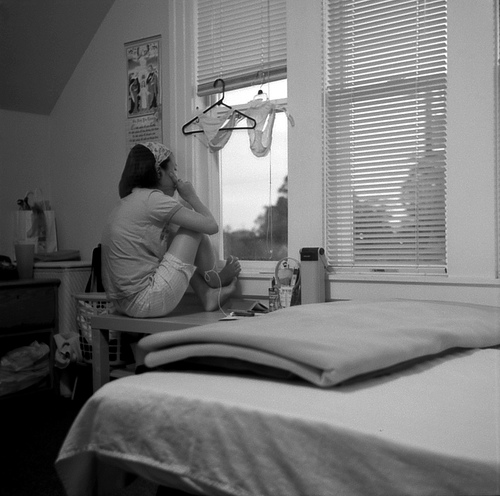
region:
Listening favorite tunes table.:
[102, 131, 240, 308]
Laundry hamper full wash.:
[68, 285, 131, 368]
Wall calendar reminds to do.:
[115, 32, 175, 142]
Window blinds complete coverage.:
[316, 3, 452, 276]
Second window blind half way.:
[174, 2, 318, 96]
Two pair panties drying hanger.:
[177, 80, 292, 160]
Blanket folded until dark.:
[135, 286, 499, 363]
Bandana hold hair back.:
[105, 134, 197, 198]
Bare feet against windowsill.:
[200, 245, 245, 311]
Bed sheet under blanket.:
[49, 373, 496, 495]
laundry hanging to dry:
[180, 86, 279, 156]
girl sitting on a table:
[102, 144, 239, 314]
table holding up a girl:
[82, 300, 251, 390]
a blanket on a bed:
[140, 290, 498, 388]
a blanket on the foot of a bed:
[140, 297, 498, 388]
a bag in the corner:
[10, 197, 60, 267]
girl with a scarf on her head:
[117, 136, 180, 202]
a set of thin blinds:
[320, 0, 447, 271]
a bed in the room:
[50, 299, 499, 491]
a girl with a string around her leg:
[192, 252, 243, 296]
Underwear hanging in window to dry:
[178, 66, 301, 158]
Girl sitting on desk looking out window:
[93, 137, 248, 321]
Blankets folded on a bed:
[129, 272, 499, 392]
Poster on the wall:
[110, 31, 175, 148]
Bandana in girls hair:
[97, 126, 193, 201]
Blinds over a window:
[322, 2, 458, 272]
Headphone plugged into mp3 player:
[184, 231, 251, 325]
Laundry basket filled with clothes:
[71, 284, 125, 363]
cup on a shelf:
[6, 237, 58, 291]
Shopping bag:
[16, 182, 67, 263]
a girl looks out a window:
[92, 114, 287, 348]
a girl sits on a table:
[84, 113, 289, 328]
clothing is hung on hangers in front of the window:
[172, 79, 309, 175]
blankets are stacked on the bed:
[158, 277, 483, 441]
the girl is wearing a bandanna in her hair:
[75, 128, 328, 324]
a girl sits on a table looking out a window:
[96, 82, 429, 354]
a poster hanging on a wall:
[99, 22, 193, 197]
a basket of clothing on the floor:
[63, 274, 163, 391]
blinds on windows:
[170, 13, 470, 309]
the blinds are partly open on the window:
[169, 13, 366, 297]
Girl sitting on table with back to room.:
[101, 130, 254, 324]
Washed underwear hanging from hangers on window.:
[182, 72, 297, 164]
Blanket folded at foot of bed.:
[137, 292, 498, 385]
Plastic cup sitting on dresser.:
[10, 235, 47, 285]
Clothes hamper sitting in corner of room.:
[73, 287, 128, 365]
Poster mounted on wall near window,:
[119, 34, 171, 169]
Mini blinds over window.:
[326, 16, 458, 278]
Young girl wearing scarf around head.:
[136, 139, 173, 176]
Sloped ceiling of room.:
[8, 9, 109, 134]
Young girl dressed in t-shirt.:
[93, 183, 189, 304]